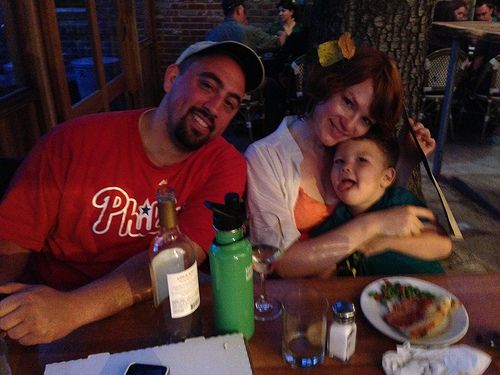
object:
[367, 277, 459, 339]
food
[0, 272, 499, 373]
table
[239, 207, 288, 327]
glass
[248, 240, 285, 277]
wine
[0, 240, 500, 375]
dining table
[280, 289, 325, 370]
glass cup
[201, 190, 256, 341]
beverage bottle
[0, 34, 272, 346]
man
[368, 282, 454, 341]
pizza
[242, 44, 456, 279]
woman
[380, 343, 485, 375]
napkin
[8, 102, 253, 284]
shirt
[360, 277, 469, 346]
plate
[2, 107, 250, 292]
red shirt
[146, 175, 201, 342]
bottle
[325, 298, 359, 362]
salt shaker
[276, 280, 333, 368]
glass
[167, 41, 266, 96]
hat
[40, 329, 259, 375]
box